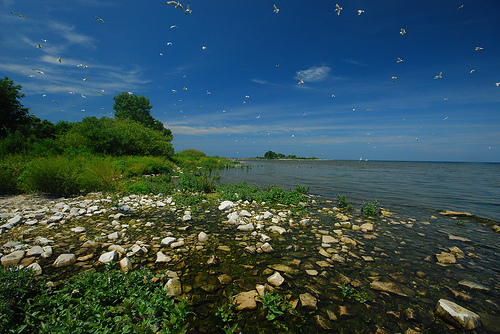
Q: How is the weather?
A: It is clear.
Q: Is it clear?
A: Yes, it is clear.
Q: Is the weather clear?
A: Yes, it is clear.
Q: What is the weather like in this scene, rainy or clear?
A: It is clear.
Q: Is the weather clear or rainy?
A: It is clear.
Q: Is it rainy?
A: No, it is clear.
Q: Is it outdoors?
A: Yes, it is outdoors.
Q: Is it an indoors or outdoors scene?
A: It is outdoors.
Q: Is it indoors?
A: No, it is outdoors.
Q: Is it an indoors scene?
A: No, it is outdoors.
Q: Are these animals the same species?
A: Yes, all the animals are birds.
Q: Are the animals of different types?
A: No, all the animals are birds.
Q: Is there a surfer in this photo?
A: No, there are no surfers.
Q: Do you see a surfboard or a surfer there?
A: No, there are no surfers or surfboards.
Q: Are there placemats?
A: No, there are no placemats.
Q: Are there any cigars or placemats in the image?
A: No, there are no placemats or cigars.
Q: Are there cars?
A: No, there are no cars.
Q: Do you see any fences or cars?
A: No, there are no cars or fences.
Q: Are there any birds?
A: Yes, there is a bird.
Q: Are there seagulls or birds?
A: Yes, there is a bird.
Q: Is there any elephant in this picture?
A: No, there are no elephants.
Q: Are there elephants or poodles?
A: No, there are no elephants or poodles.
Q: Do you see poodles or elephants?
A: No, there are no elephants or poodles.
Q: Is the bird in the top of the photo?
A: Yes, the bird is in the top of the image.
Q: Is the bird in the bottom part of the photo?
A: No, the bird is in the top of the image.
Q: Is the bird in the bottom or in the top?
A: The bird is in the top of the image.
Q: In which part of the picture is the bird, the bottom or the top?
A: The bird is in the top of the image.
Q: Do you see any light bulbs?
A: No, there are no light bulbs.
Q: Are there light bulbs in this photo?
A: No, there are no light bulbs.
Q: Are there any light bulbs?
A: No, there are no light bulbs.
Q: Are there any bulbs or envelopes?
A: No, there are no bulbs or envelopes.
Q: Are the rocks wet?
A: Yes, the rocks are wet.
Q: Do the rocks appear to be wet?
A: Yes, the rocks are wet.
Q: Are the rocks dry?
A: No, the rocks are wet.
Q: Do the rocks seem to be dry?
A: No, the rocks are wet.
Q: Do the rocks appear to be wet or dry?
A: The rocks are wet.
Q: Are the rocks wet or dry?
A: The rocks are wet.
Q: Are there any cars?
A: No, there are no cars.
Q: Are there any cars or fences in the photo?
A: No, there are no cars or fences.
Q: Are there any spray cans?
A: No, there are no spray cans.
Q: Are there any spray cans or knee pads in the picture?
A: No, there are no spray cans or knee pads.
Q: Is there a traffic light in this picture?
A: No, there are no traffic lights.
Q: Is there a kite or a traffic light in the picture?
A: No, there are no traffic lights or kites.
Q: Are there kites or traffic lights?
A: No, there are no traffic lights or kites.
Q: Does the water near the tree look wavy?
A: No, the water is calm.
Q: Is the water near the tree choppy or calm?
A: The water is calm.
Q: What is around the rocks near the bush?
A: The water is around the rocks.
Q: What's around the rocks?
A: The water is around the rocks.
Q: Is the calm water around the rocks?
A: Yes, the water is around the rocks.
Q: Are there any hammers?
A: No, there are no hammers.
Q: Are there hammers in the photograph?
A: No, there are no hammers.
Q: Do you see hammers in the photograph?
A: No, there are no hammers.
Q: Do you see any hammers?
A: No, there are no hammers.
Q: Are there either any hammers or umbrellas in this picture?
A: No, there are no hammers or umbrellas.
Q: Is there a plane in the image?
A: No, there are no airplanes.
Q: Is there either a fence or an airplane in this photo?
A: No, there are no airplanes or fences.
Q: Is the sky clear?
A: Yes, the sky is clear.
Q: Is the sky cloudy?
A: No, the sky is clear.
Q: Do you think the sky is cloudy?
A: No, the sky is clear.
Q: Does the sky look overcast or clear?
A: The sky is clear.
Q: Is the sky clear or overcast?
A: The sky is clear.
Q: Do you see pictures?
A: No, there are no pictures.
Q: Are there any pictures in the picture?
A: No, there are no pictures.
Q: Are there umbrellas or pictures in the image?
A: No, there are no pictures or umbrellas.